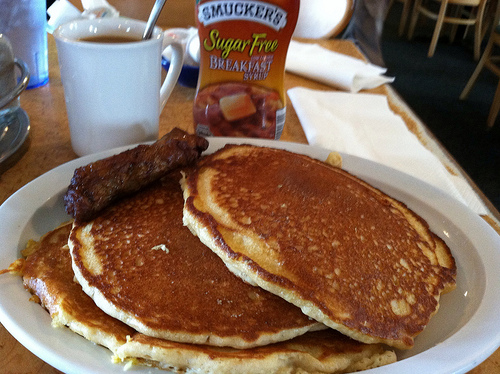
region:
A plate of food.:
[21, 10, 438, 370]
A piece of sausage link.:
[56, 118, 204, 221]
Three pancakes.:
[43, 146, 460, 356]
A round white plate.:
[4, 121, 496, 364]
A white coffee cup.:
[45, 13, 180, 141]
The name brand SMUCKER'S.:
[185, 1, 286, 26]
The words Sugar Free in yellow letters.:
[201, 25, 281, 55]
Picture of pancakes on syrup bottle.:
[195, 72, 280, 128]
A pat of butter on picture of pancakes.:
[217, 82, 253, 118]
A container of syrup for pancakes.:
[189, 0, 301, 137]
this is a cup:
[60, 30, 169, 134]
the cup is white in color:
[73, 59, 145, 125]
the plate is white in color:
[449, 302, 496, 357]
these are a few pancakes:
[163, 171, 448, 363]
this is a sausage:
[60, 126, 205, 229]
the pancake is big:
[216, 150, 437, 343]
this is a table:
[34, 90, 57, 166]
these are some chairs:
[417, 2, 498, 116]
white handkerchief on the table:
[307, 92, 395, 142]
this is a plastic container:
[200, 25, 286, 135]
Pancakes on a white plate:
[43, 140, 472, 372]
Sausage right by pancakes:
[32, 116, 382, 311]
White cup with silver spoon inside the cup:
[42, 11, 196, 156]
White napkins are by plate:
[290, 73, 476, 219]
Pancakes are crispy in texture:
[67, 154, 478, 372]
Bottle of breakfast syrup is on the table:
[188, 3, 317, 152]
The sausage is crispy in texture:
[51, 105, 225, 223]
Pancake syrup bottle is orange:
[185, 3, 298, 146]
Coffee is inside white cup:
[52, 10, 175, 88]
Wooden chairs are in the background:
[404, 2, 496, 119]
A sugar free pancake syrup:
[197, 3, 289, 133]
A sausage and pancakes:
[62, 162, 351, 372]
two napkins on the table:
[293, 40, 401, 137]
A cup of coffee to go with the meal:
[60, 8, 273, 363]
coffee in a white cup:
[56, 24, 183, 116]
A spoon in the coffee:
[63, 9, 171, 125]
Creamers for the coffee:
[168, 27, 200, 83]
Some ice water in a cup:
[2, 1, 41, 81]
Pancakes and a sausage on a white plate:
[31, 142, 461, 357]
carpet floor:
[405, 55, 458, 105]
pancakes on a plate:
[9, 110, 497, 367]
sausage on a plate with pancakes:
[55, 104, 207, 203]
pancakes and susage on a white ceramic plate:
[0, 131, 498, 366]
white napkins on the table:
[303, 34, 440, 181]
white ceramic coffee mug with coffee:
[34, 18, 166, 155]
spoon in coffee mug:
[113, 1, 170, 53]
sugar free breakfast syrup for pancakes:
[177, 0, 297, 145]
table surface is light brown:
[25, 91, 69, 156]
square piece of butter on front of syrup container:
[212, 87, 262, 127]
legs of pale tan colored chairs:
[410, 1, 488, 123]